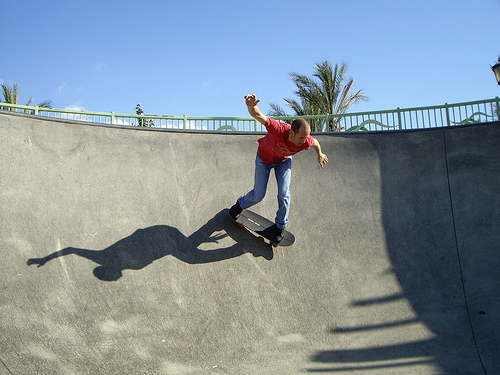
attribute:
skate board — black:
[250, 211, 261, 232]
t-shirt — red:
[271, 125, 287, 151]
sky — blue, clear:
[31, 1, 472, 60]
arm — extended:
[251, 106, 270, 123]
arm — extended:
[315, 143, 328, 157]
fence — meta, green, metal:
[372, 109, 486, 124]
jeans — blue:
[259, 164, 265, 191]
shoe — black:
[233, 209, 239, 219]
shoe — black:
[273, 228, 281, 240]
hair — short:
[295, 121, 303, 129]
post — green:
[108, 111, 115, 123]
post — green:
[395, 110, 406, 128]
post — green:
[443, 109, 453, 124]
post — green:
[182, 118, 195, 129]